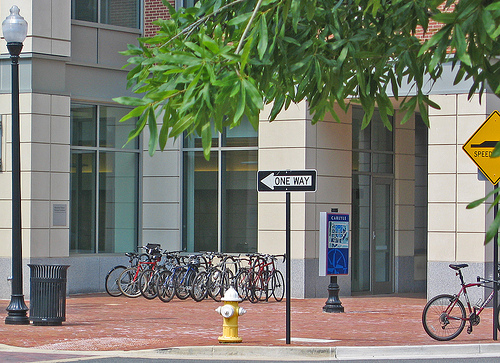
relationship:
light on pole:
[2, 4, 30, 59] [4, 43, 31, 327]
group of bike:
[107, 242, 287, 300] [121, 254, 147, 298]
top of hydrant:
[220, 286, 243, 303] [215, 286, 248, 342]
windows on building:
[67, 98, 396, 293] [0, 1, 495, 307]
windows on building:
[74, 1, 143, 37] [0, 1, 495, 307]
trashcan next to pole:
[28, 263, 68, 326] [4, 43, 31, 327]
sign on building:
[53, 203, 69, 230] [0, 1, 495, 307]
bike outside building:
[121, 254, 147, 298] [0, 1, 495, 307]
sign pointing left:
[257, 170, 317, 192] [0, 2, 78, 360]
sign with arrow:
[257, 170, 317, 192] [262, 171, 314, 189]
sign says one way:
[257, 170, 317, 192] [274, 177, 309, 186]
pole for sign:
[285, 193, 292, 347] [257, 170, 317, 192]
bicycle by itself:
[420, 263, 499, 340] [422, 261, 499, 336]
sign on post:
[460, 110, 499, 185] [489, 185, 499, 340]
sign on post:
[257, 170, 317, 192] [285, 193, 292, 347]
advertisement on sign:
[329, 218, 349, 257] [319, 210, 348, 277]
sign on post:
[319, 210, 348, 277] [323, 276, 342, 314]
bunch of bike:
[107, 242, 287, 300] [121, 254, 147, 298]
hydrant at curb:
[215, 286, 248, 342] [163, 347, 499, 358]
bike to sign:
[420, 263, 499, 340] [460, 110, 499, 185]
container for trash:
[28, 263, 68, 326] [40, 282, 71, 310]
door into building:
[371, 181, 391, 292] [0, 1, 495, 307]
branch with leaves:
[161, 1, 268, 65] [111, 2, 499, 160]